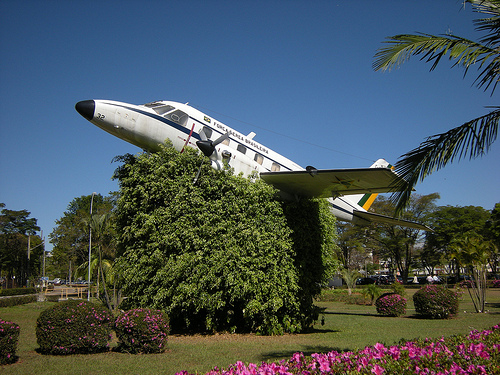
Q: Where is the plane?
A: In the tree.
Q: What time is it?
A: Afternoon.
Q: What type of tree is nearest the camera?
A: Palm tree.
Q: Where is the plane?
A: In a bush.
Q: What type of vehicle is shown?
A: Plane.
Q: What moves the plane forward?
A: Propeller.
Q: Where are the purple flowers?
A: In bushes.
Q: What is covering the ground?
A: Grass.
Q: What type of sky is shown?
A: Clear.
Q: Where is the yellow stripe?
A: Plane's tail.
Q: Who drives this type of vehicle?
A: Pilot.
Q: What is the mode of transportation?
A: Plane.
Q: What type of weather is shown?
A: Clear.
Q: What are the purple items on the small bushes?
A: Flowers.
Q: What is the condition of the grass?
A: Well manicured.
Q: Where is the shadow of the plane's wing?
A: On the tree beneath the plane.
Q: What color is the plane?
A: White.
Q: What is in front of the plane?
A: A bush.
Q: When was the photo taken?
A: Daytime.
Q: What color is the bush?
A: Green.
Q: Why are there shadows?
A: It is sunny.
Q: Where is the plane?
A: Behind the bush.